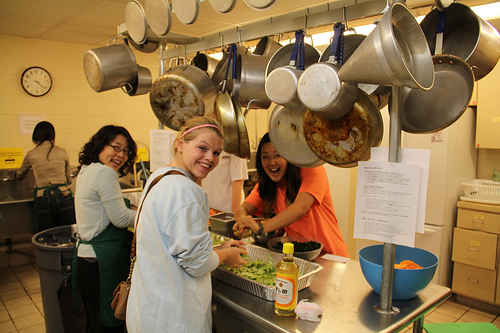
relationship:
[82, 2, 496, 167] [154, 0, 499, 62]
pots on rack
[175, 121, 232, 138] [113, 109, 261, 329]
headband on girl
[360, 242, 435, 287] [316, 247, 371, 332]
blue bowl on counter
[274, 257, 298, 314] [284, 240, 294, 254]
oil with cap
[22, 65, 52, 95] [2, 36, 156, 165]
clock on wall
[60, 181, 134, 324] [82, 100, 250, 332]
apron on woman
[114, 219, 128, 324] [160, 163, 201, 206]
purse on shoulder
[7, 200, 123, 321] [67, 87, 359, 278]
trash can behind girls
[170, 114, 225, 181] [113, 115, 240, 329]
head of woman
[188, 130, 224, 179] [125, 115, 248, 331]
face of woman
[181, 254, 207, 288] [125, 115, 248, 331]
elbow of woman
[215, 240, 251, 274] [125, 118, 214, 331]
hand of woman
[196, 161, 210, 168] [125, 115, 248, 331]
teeth of woman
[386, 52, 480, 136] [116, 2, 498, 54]
pan hanging on rack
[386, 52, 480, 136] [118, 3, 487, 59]
pan hanging on rack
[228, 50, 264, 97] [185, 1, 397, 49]
pan hanging on rack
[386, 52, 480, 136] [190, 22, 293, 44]
pan hanging on rack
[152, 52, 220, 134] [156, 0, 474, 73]
pan hanging on rack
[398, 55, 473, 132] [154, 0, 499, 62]
pan hanging on rack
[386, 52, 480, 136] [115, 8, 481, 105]
pan hanging on rack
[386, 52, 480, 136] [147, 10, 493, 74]
pan hanging on rack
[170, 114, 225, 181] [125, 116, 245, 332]
head of person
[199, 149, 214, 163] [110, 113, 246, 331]
nose of person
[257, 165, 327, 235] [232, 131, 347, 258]
arm of person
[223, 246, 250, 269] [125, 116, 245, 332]
hand of person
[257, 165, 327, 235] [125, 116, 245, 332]
arm of person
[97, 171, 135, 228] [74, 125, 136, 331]
arm of person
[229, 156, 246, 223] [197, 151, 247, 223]
arm of person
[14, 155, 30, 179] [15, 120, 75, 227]
arm of person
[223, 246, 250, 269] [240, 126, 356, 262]
hand of person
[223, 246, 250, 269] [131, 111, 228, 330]
hand of person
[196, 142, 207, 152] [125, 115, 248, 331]
eye of woman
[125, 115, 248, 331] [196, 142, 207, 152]
woman has an eye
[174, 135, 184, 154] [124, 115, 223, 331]
ear of a woman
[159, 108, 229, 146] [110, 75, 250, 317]
hair of a woman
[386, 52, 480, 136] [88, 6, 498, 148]
pan on a rack